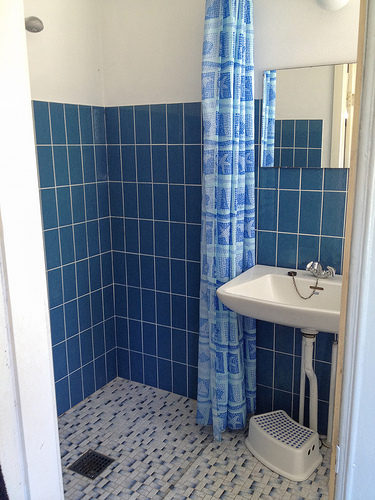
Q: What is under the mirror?
A: A sink.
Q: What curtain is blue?
A: The shower curtain.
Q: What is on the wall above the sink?
A: A mirro.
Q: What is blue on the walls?
A: The tile.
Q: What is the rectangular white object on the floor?
A: A footstool.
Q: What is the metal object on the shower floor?
A: The drain.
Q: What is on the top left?
A: A shower head.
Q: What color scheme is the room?
A: Blue and white.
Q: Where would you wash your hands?
A: Sink.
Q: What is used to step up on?
A: Stool.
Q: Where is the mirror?
A: Above the sink.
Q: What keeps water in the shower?
A: Shower curtain.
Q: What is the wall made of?
A: Blue tiles.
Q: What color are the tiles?
A: Blue.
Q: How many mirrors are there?
A: Oe.